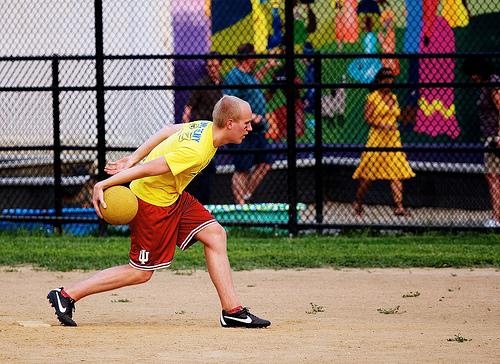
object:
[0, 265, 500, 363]
dirt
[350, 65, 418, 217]
woman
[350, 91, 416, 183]
dress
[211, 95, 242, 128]
hair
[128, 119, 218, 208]
t-shirt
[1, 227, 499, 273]
green grass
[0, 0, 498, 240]
fence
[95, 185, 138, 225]
kickball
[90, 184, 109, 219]
hand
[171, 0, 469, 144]
painting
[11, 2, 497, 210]
wall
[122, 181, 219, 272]
shorts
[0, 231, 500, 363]
field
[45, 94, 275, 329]
boy